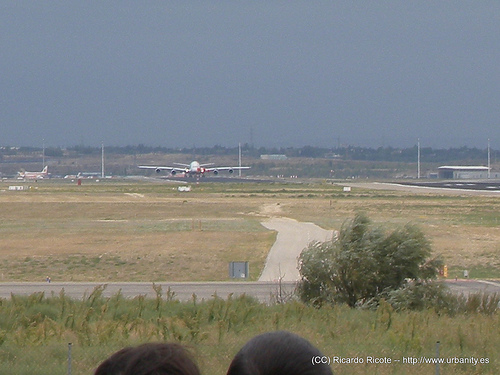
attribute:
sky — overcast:
[235, 24, 407, 121]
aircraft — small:
[12, 164, 57, 184]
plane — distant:
[107, 139, 287, 207]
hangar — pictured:
[435, 157, 487, 182]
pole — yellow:
[441, 262, 450, 276]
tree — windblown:
[295, 202, 487, 301]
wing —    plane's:
[136, 163, 187, 176]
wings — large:
[138, 165, 251, 173]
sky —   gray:
[298, 36, 389, 90]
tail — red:
[194, 166, 204, 175]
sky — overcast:
[3, 0, 499, 152]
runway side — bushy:
[8, 280, 497, 303]